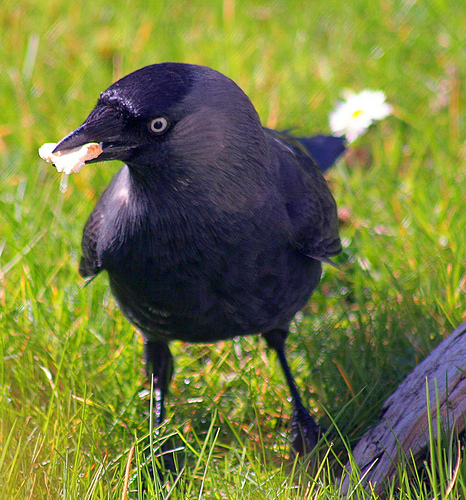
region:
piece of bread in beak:
[40, 120, 115, 193]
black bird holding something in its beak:
[73, 74, 323, 364]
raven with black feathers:
[68, 54, 344, 467]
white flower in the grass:
[322, 84, 405, 143]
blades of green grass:
[37, 394, 204, 496]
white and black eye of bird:
[148, 111, 173, 138]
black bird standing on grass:
[70, 65, 362, 376]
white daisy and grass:
[315, 91, 410, 165]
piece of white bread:
[33, 132, 104, 171]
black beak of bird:
[59, 99, 146, 176]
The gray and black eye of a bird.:
[149, 116, 169, 133]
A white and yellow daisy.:
[328, 88, 393, 143]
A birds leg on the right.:
[264, 323, 336, 470]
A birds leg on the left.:
[139, 337, 182, 479]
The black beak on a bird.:
[53, 99, 140, 164]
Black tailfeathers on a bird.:
[285, 121, 349, 168]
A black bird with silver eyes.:
[51, 61, 352, 475]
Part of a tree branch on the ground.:
[330, 320, 465, 490]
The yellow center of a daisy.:
[350, 106, 365, 119]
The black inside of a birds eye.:
[151, 119, 163, 130]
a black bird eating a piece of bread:
[29, 52, 338, 491]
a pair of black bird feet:
[103, 321, 338, 481]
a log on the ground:
[316, 260, 465, 485]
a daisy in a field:
[301, 67, 436, 158]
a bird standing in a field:
[26, 66, 343, 466]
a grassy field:
[5, 329, 94, 439]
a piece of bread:
[10, 121, 138, 187]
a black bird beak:
[25, 65, 153, 175]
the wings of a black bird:
[34, 171, 415, 282]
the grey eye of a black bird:
[135, 117, 190, 147]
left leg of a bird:
[289, 368, 292, 385]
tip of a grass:
[77, 454, 88, 458]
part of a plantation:
[89, 427, 102, 435]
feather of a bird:
[206, 320, 210, 323]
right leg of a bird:
[165, 375, 173, 402]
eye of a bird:
[160, 121, 171, 129]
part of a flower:
[352, 95, 370, 114]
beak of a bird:
[80, 129, 103, 145]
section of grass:
[282, 462, 303, 473]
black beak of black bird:
[37, 102, 134, 177]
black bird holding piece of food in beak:
[18, 54, 357, 493]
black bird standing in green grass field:
[32, 46, 355, 494]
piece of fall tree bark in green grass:
[346, 323, 464, 490]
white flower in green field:
[328, 82, 393, 149]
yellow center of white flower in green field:
[345, 108, 369, 122]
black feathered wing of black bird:
[256, 125, 346, 261]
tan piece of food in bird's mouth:
[34, 138, 103, 175]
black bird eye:
[140, 105, 172, 139]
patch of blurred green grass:
[17, 13, 99, 99]